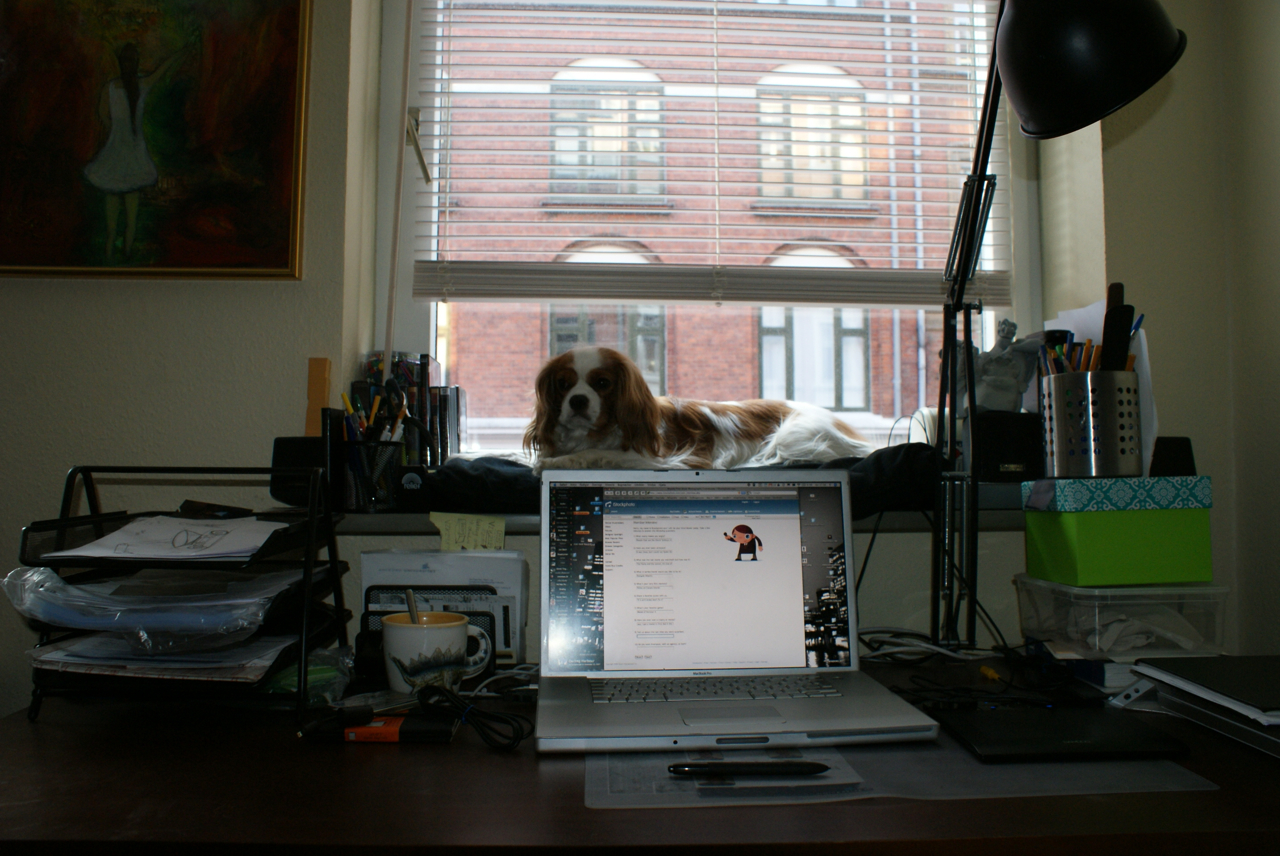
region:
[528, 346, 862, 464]
dog sitting on the windowsill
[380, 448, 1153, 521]
a window sill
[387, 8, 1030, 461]
a window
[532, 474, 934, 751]
silver laptop computer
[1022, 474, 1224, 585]
a green box with a decorative lid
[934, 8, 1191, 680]
a black desk lamp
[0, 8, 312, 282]
a painting of a girl left of the window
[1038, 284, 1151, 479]
silver container full of pens and pencils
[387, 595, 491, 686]
a white mug on the desk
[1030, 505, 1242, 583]
bottom of box is green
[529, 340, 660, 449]
dog has a head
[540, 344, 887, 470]
dog is white and brown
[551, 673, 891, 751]
keyboard is white in color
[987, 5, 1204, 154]
lamp is black in color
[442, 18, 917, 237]
building has windows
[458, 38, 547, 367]
building is red in color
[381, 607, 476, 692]
cup is white in color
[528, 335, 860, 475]
a brown and white dog sitting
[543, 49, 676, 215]
the window of the building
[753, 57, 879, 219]
the window of the building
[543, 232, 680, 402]
the window of the building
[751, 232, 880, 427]
the window of the building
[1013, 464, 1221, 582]
the blue and green box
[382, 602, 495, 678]
the white and orange mug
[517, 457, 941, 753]
the sulver laptop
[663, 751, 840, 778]
the black pen